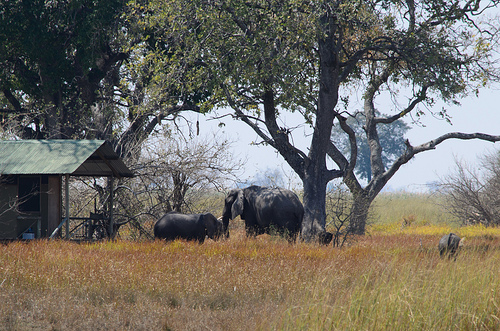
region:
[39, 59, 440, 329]
elephants standing in the grass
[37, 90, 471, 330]
elephants by a house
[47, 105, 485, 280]
elephants in front of a house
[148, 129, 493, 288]
a small and large elephant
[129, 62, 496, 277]
elephants next trees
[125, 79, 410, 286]
elephants next to a tree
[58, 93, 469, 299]
elephants under a tree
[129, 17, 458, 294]
a tree with leaves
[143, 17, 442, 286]
tree with green leaves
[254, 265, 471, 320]
a field of green grass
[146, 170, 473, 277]
a momma elephant & her babies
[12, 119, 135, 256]
an old house is in the photo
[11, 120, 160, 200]
the roof is green tin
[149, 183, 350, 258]
the big elephant is taking care of the baby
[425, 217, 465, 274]
another little elephant is grazing a distance away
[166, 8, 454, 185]
the tree is very large & creates shade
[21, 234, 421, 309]
the grass appears tall & unkempt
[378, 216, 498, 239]
yellow flowers bloom in the midground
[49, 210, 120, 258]
the house has a railing on one side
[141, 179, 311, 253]
the elephants are grey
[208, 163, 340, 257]
elephant with shadows on its back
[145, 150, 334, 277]
two elephants in a grassy field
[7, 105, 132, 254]
green roof of a hut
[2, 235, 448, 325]
grassy plain with elephants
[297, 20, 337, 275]
tree trunk of a tree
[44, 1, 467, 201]
group of tree's in a field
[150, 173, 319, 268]
two elephants facing each other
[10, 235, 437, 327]
grassy plain full of grass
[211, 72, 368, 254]
elephant standing next to a tree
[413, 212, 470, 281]
small animal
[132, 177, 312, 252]
two elephants standing together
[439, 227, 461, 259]
another small elephant wandering around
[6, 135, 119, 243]
a house next to the animals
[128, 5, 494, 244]
a big tall tree with a lot of leaves on it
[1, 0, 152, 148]
a tree with a lot of green leaves on it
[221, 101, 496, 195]
some blue sky in the background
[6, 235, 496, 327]
the grass of the field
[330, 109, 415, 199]
another tree in the background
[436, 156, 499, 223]
a leafless bush off to the side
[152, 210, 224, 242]
a very cute baby elephant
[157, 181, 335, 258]
two elephants in field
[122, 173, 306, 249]
elephants are dark grey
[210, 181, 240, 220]
elephant has light grey ear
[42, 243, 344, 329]
grass is light brown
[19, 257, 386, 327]
grass is thin and wispy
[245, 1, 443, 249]
tall tree next to elephant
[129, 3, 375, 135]
green leaves on tree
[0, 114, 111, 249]
small building next to elephants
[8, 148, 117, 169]
building has light green roof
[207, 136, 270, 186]
grey sky behind elephants